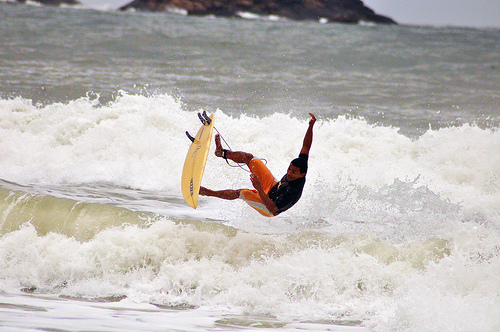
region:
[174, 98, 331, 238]
a man surfing in the water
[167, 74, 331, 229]
a man surfing in the ocean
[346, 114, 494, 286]
a white wave in the water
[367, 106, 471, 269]
a white wave in the ocean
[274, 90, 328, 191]
a man with his arm stretched out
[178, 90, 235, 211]
a yellow surf board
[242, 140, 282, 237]
a man wearing orange and white shorts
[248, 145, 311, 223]
a man wearing a black shirt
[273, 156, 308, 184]
a man with black hair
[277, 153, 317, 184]
a man with short hair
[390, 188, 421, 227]
part of a splaskj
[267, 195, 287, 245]
part of an elbow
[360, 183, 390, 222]
part of a spalsj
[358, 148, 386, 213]
part of a watef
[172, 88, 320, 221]
person in a wet suit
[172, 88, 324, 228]
person on a surf board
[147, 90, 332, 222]
person with a rope ankored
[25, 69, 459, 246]
waves of an ocean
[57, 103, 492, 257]
strong tidal wave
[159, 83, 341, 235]
person is maneuvering on board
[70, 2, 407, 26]
a rocky platform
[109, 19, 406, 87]
body of water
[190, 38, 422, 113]
body of ocean water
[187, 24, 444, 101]
body of sea salt water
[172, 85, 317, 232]
Guy is on surfboard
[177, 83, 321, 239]
Guy is mid air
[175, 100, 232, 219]
The surfboard is yellow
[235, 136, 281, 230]
Swim trunks are orange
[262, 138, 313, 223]
Wet suit is black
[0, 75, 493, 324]
The waves are crashing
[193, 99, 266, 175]
The surfboard is strapped to him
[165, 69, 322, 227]
The surfer has his hand in the air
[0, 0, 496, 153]
The water is grey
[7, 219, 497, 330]
The crashing waves are white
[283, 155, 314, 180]
Man has short hair.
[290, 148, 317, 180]
Man has dark hair.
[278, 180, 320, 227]
Man wearing black shirt.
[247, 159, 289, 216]
Man wearing orange shorts.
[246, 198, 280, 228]
White stripe on orange shorts.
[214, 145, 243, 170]
Black band around man's ankle.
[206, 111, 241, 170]
Black cord attached to band.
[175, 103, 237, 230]
Person surfing in water.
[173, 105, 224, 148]
Black fins on bottom of board.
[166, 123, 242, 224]
Surfboard is yellow in color.